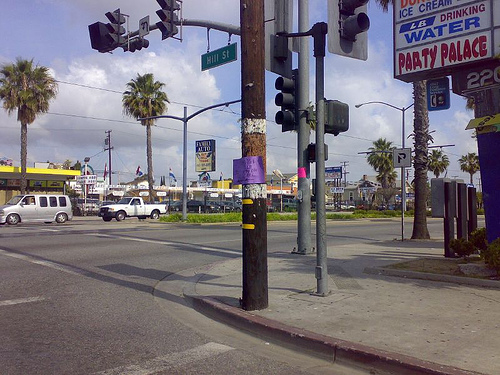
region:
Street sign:
[382, 4, 494, 81]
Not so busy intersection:
[0, 183, 245, 345]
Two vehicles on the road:
[3, 189, 225, 231]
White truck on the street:
[91, 183, 257, 230]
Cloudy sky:
[12, 3, 284, 155]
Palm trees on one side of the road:
[3, 50, 237, 237]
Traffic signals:
[77, 2, 395, 267]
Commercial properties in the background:
[15, 120, 424, 232]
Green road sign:
[170, 36, 257, 84]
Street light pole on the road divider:
[112, 102, 240, 226]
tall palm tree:
[122, 72, 167, 201]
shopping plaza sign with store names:
[393, 2, 499, 87]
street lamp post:
[133, 105, 225, 226]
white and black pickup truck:
[101, 191, 169, 220]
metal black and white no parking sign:
[391, 145, 412, 217]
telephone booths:
[428, 172, 469, 256]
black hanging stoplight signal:
[149, 0, 188, 47]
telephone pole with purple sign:
[237, 1, 271, 309]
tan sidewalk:
[366, 275, 498, 373]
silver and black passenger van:
[5, 191, 80, 225]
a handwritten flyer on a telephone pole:
[231, 142, 272, 314]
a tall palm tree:
[123, 74, 168, 201]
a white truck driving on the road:
[101, 195, 169, 222]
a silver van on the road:
[0, 192, 76, 227]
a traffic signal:
[273, 58, 350, 255]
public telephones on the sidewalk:
[430, 175, 480, 257]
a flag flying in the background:
[165, 163, 180, 183]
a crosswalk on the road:
[0, 223, 246, 309]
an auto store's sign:
[193, 138, 216, 173]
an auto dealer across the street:
[100, 134, 242, 211]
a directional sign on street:
[396, 36, 493, 71]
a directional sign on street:
[197, 39, 236, 69]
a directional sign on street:
[191, 133, 220, 176]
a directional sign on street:
[322, 156, 349, 203]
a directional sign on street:
[386, 2, 487, 42]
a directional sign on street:
[411, 80, 458, 113]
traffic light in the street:
[83, 4, 132, 54]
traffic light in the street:
[151, 0, 187, 45]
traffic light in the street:
[266, 68, 301, 136]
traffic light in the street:
[343, 0, 372, 45]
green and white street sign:
[199, 40, 238, 71]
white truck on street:
[102, 194, 166, 217]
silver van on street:
[0, 194, 70, 224]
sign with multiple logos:
[391, 0, 498, 73]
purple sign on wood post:
[231, 157, 263, 184]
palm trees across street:
[0, 55, 160, 197]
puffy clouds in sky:
[0, 0, 490, 181]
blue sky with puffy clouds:
[0, 0, 499, 175]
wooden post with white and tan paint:
[237, 0, 273, 312]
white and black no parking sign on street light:
[392, 147, 412, 169]